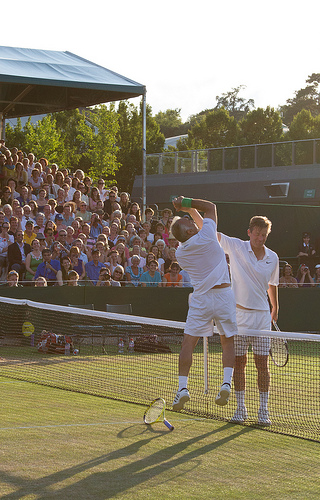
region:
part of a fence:
[279, 387, 285, 393]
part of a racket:
[168, 410, 170, 417]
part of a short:
[193, 313, 197, 318]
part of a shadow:
[147, 440, 158, 457]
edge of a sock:
[230, 364, 236, 380]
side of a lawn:
[216, 429, 221, 435]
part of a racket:
[156, 416, 162, 423]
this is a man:
[184, 193, 310, 433]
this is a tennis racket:
[122, 365, 196, 474]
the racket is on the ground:
[131, 375, 179, 438]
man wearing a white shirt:
[212, 235, 281, 321]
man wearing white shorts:
[230, 294, 278, 359]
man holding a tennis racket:
[257, 292, 299, 375]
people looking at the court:
[9, 140, 285, 332]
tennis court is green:
[3, 319, 319, 499]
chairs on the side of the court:
[41, 261, 154, 359]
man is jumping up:
[154, 184, 273, 443]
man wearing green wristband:
[166, 193, 224, 261]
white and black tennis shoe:
[169, 387, 195, 411]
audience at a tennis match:
[0, 203, 139, 264]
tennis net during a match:
[13, 298, 145, 403]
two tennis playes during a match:
[169, 187, 284, 432]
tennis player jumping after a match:
[159, 188, 241, 432]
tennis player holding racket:
[215, 215, 290, 428]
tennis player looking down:
[247, 213, 271, 257]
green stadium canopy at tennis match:
[2, 50, 146, 110]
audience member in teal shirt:
[142, 258, 163, 287]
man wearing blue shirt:
[90, 266, 97, 272]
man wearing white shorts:
[211, 302, 220, 309]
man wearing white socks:
[179, 376, 186, 385]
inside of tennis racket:
[152, 409, 156, 414]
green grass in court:
[47, 396, 63, 409]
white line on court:
[71, 418, 84, 430]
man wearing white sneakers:
[229, 403, 274, 427]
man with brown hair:
[251, 215, 269, 227]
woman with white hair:
[117, 266, 123, 270]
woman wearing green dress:
[29, 257, 35, 263]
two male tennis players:
[137, 170, 297, 446]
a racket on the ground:
[144, 380, 195, 448]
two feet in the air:
[158, 372, 262, 410]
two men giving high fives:
[136, 176, 297, 442]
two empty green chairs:
[60, 272, 173, 372]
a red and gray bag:
[19, 321, 77, 363]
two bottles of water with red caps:
[107, 331, 135, 359]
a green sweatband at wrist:
[181, 197, 198, 210]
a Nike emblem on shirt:
[258, 256, 281, 275]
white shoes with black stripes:
[162, 379, 205, 417]